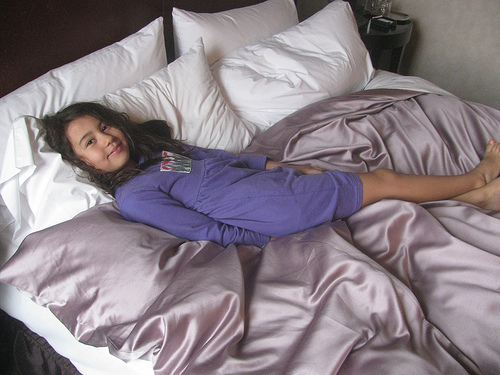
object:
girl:
[36, 101, 500, 248]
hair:
[21, 102, 197, 197]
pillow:
[211, 0, 378, 130]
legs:
[450, 189, 479, 206]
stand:
[361, 11, 416, 74]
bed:
[0, 0, 500, 375]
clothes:
[112, 144, 364, 246]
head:
[38, 101, 130, 172]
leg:
[294, 167, 469, 233]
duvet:
[1, 88, 500, 375]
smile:
[107, 141, 126, 158]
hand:
[294, 164, 327, 176]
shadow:
[416, 24, 435, 73]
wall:
[407, 22, 500, 112]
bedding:
[0, 0, 500, 369]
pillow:
[0, 37, 254, 233]